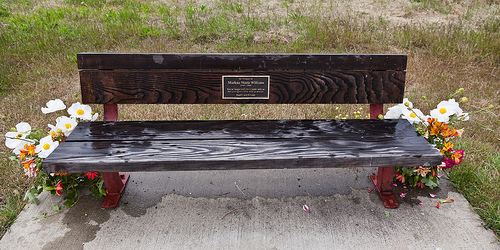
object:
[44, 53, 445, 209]
bench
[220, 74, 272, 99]
plaque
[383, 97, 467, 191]
flowers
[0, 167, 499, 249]
concrete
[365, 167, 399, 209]
metal legs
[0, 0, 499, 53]
grass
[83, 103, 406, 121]
gap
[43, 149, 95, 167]
edge